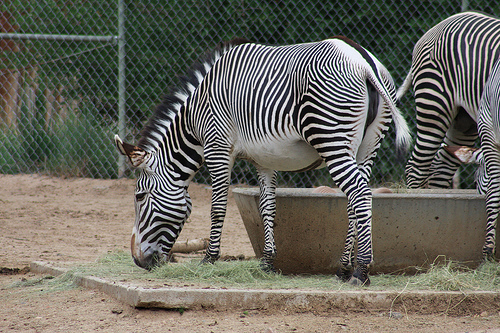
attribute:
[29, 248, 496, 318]
platform — stone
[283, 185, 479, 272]
gray tub — grey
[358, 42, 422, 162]
tail — white, black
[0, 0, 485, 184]
fence — chain link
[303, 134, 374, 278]
legs — black, white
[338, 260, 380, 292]
hooves — black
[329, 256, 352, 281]
hooves — black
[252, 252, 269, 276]
hooves — black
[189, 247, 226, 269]
hooves — black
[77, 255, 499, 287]
grass — green